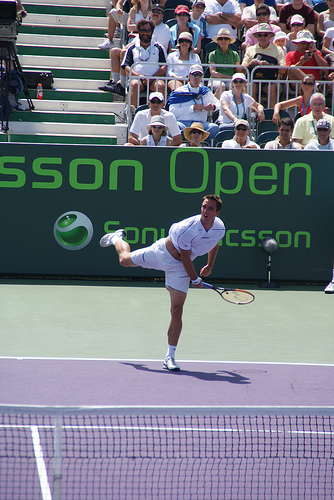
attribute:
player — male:
[98, 194, 226, 374]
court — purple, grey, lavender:
[4, 357, 330, 498]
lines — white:
[1, 357, 333, 498]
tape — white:
[1, 403, 333, 418]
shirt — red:
[284, 49, 329, 78]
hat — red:
[172, 2, 189, 19]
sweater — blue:
[168, 23, 202, 46]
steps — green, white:
[5, 3, 125, 145]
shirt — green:
[208, 48, 239, 75]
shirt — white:
[171, 216, 226, 261]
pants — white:
[130, 238, 194, 293]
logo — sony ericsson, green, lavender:
[50, 211, 94, 254]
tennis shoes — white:
[99, 227, 180, 372]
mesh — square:
[4, 414, 332, 499]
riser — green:
[16, 44, 114, 58]